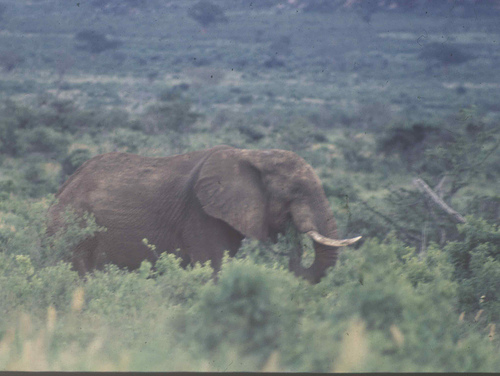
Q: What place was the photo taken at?
A: It was taken at the plain.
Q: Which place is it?
A: It is a plain.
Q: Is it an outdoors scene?
A: Yes, it is outdoors.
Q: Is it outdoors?
A: Yes, it is outdoors.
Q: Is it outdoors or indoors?
A: It is outdoors.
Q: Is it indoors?
A: No, it is outdoors.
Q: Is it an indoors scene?
A: No, it is outdoors.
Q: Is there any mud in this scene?
A: Yes, there is mud.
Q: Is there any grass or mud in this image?
A: Yes, there is mud.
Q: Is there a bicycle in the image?
A: No, there are no bicycles.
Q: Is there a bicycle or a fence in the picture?
A: No, there are no bicycles or fences.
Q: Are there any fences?
A: No, there are no fences.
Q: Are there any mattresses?
A: No, there are no mattresses.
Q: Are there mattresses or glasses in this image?
A: No, there are no mattresses or glasses.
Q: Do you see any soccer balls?
A: No, there are no soccer balls.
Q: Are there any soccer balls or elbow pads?
A: No, there are no soccer balls or elbow pads.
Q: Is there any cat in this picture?
A: No, there are no cats.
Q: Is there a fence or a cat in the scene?
A: No, there are no cats or fences.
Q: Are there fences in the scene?
A: No, there are no fences.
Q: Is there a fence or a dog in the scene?
A: No, there are no fences or dogs.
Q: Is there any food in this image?
A: Yes, there is food.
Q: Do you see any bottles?
A: No, there are no bottles.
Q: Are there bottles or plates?
A: No, there are no bottles or plates.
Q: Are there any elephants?
A: Yes, there is an elephant.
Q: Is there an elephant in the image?
A: Yes, there is an elephant.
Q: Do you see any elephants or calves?
A: Yes, there is an elephant.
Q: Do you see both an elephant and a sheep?
A: No, there is an elephant but no sheep.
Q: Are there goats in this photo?
A: No, there are no goats.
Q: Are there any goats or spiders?
A: No, there are no goats or spiders.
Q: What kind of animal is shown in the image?
A: The animal is an elephant.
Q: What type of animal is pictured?
A: The animal is an elephant.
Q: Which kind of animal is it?
A: The animal is an elephant.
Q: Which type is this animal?
A: This is an elephant.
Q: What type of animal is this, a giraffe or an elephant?
A: This is an elephant.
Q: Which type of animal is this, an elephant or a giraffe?
A: This is an elephant.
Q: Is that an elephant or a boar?
A: That is an elephant.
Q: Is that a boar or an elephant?
A: That is an elephant.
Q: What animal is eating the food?
A: The elephant is eating the food.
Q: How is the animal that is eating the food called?
A: The animal is an elephant.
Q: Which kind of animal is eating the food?
A: The animal is an elephant.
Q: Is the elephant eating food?
A: Yes, the elephant is eating food.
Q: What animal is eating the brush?
A: The elephant is eating the brush.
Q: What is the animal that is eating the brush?
A: The animal is an elephant.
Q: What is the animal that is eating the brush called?
A: The animal is an elephant.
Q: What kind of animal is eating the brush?
A: The animal is an elephant.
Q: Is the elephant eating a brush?
A: Yes, the elephant is eating a brush.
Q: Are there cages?
A: No, there are no cages.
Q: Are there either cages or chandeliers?
A: No, there are no cages or chandeliers.